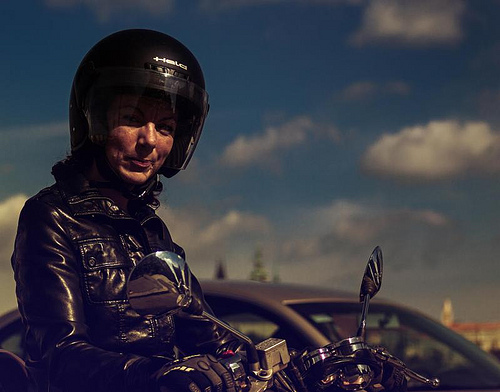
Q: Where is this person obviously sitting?
A: On motorcycle.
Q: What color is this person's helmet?
A: Black.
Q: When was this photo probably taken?
A: Early evening.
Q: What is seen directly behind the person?
A: Automobile.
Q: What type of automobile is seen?
A: Car.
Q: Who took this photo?
A: Photographer.